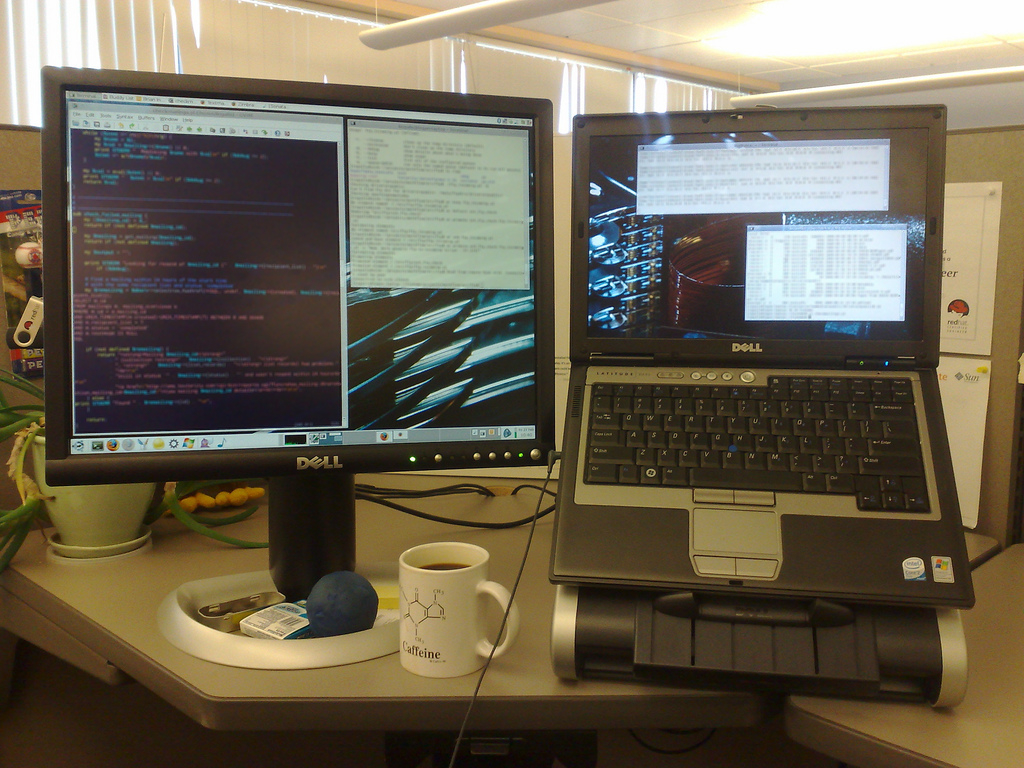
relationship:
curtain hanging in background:
[4, 3, 635, 138] [4, 3, 987, 297]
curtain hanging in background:
[637, 74, 754, 114] [4, 3, 987, 297]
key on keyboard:
[678, 410, 705, 432] [538, 90, 988, 622]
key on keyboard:
[716, 398, 738, 417] [538, 90, 988, 622]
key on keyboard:
[749, 410, 780, 445] [538, 90, 988, 622]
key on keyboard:
[754, 406, 791, 445] [538, 90, 988, 622]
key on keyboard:
[792, 388, 829, 432] [538, 90, 988, 622]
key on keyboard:
[767, 425, 804, 460] [538, 90, 988, 622]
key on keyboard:
[760, 447, 795, 476] [538, 90, 988, 622]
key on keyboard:
[715, 444, 746, 479] [538, 90, 988, 622]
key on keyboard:
[619, 440, 661, 477] [538, 90, 988, 622]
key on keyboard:
[680, 419, 713, 454] [538, 90, 988, 622]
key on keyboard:
[760, 444, 793, 486] [538, 90, 988, 622]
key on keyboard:
[686, 382, 715, 415] [538, 90, 988, 622]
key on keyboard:
[626, 379, 668, 427] [578, 377, 944, 509]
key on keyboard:
[706, 392, 728, 416] [577, 370, 938, 515]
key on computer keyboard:
[768, 451, 792, 473] [589, 370, 932, 556]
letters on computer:
[728, 335, 761, 357] [546, 102, 981, 614]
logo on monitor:
[281, 443, 359, 472] [28, 52, 564, 487]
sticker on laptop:
[922, 540, 959, 592] [523, 343, 984, 719]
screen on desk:
[28, 52, 571, 573] [8, 476, 992, 753]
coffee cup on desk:
[395, 538, 528, 686] [39, 476, 807, 764]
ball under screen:
[302, 562, 383, 638] [21, 44, 583, 531]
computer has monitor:
[32, 52, 988, 703] [73, 90, 553, 477]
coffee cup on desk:
[395, 538, 528, 686] [20, 514, 1021, 763]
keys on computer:
[586, 363, 936, 511] [546, 102, 981, 614]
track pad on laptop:
[684, 497, 790, 569] [541, 111, 948, 611]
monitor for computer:
[28, 52, 564, 487] [543, 87, 969, 604]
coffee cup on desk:
[395, 538, 528, 686] [83, 454, 995, 740]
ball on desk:
[314, 562, 384, 632] [33, 497, 995, 750]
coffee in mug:
[407, 549, 472, 567] [385, 543, 537, 662]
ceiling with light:
[130, 22, 932, 83] [684, 16, 993, 53]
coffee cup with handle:
[396, 538, 530, 673] [478, 573, 513, 654]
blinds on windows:
[163, 22, 334, 68] [76, 7, 720, 114]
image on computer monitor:
[133, 117, 537, 426] [53, 80, 574, 459]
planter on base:
[16, 409, 168, 556] [55, 523, 153, 556]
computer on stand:
[546, 102, 981, 614] [548, 569, 976, 704]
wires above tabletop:
[400, 472, 537, 531] [102, 526, 597, 719]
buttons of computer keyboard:
[580, 359, 941, 519] [589, 370, 933, 556]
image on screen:
[651, 163, 874, 310] [602, 135, 911, 330]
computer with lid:
[546, 102, 981, 614] [560, 89, 956, 357]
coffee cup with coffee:
[395, 538, 528, 686] [406, 549, 471, 567]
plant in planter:
[16, 418, 105, 449] [16, 409, 167, 556]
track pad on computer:
[683, 497, 789, 569] [546, 102, 981, 614]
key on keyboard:
[615, 405, 639, 419] [577, 370, 938, 515]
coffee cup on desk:
[395, 538, 528, 686] [8, 476, 992, 753]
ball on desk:
[302, 562, 383, 638] [17, 450, 992, 749]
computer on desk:
[546, 102, 981, 614] [8, 476, 992, 753]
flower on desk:
[8, 404, 264, 564] [8, 476, 992, 753]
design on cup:
[401, 577, 462, 660] [402, 536, 521, 683]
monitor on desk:
[39, 64, 560, 676] [8, 476, 992, 753]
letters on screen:
[287, 446, 340, 472] [36, 61, 562, 474]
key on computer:
[715, 448, 748, 474] [546, 102, 981, 614]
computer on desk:
[546, 102, 981, 614] [7, 399, 993, 758]